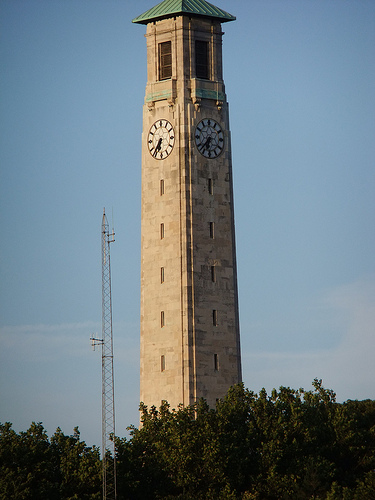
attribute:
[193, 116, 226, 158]
clock — white 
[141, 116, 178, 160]
clock — white 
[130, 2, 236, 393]
tower — large 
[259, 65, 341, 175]
sky — blue 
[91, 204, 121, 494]
tower — metal 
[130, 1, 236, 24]
roof — green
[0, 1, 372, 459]
sky — Blue 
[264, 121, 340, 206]
sky — blue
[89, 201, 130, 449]
tower — wire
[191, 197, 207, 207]
brick — white 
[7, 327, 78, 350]
clouds — white 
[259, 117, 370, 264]
sky — blue 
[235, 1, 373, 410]
sky — blue 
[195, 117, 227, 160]
face — white , black 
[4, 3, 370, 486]
tower — big 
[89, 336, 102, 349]
support — metal 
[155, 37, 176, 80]
window — narrow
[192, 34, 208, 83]
window — narrow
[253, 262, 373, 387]
clouds — white